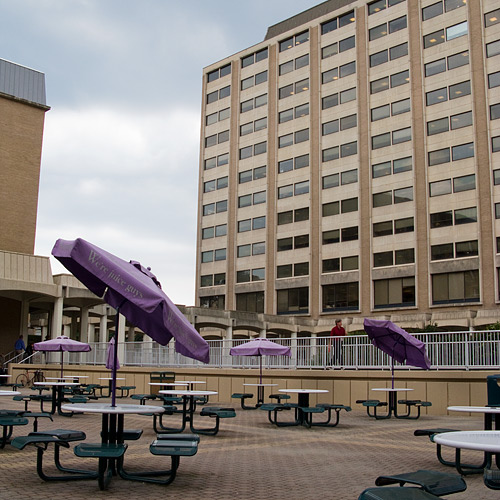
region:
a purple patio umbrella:
[50, 235, 210, 405]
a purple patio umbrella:
[363, 319, 432, 389]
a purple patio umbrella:
[229, 335, 291, 384]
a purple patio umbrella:
[33, 334, 90, 384]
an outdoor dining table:
[7, 401, 197, 487]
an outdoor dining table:
[258, 388, 350, 428]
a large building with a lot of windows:
[194, 0, 499, 366]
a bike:
[15, 367, 47, 390]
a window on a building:
[372, 275, 415, 311]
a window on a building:
[276, 287, 309, 317]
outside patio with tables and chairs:
[47, 223, 409, 467]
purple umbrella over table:
[36, 246, 266, 430]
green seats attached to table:
[79, 320, 256, 498]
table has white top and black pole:
[53, 381, 236, 493]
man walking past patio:
[297, 293, 443, 420]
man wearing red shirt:
[287, 301, 406, 425]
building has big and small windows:
[210, 140, 498, 381]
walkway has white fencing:
[182, 313, 435, 410]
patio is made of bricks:
[9, 386, 281, 491]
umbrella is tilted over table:
[51, 205, 276, 426]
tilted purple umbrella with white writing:
[50, 235, 215, 364]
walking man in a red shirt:
[327, 317, 348, 370]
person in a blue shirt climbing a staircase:
[11, 331, 29, 359]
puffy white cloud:
[41, 105, 211, 200]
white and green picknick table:
[10, 395, 205, 497]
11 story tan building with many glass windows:
[190, 0, 499, 367]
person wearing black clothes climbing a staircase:
[22, 337, 35, 363]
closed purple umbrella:
[101, 335, 124, 377]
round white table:
[54, 395, 169, 424]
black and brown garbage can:
[147, 367, 179, 398]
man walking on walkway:
[317, 301, 347, 377]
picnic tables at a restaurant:
[39, 237, 288, 479]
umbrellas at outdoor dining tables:
[41, 232, 286, 369]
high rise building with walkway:
[167, 22, 492, 322]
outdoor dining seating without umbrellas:
[268, 384, 489, 492]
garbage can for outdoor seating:
[144, 359, 185, 403]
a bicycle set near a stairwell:
[11, 365, 56, 391]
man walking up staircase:
[5, 293, 31, 370]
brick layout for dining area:
[226, 402, 406, 492]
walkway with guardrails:
[61, 335, 470, 389]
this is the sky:
[69, 13, 177, 67]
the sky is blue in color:
[88, 50, 143, 72]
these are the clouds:
[54, 115, 122, 147]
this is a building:
[210, 67, 494, 277]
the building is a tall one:
[277, 26, 374, 310]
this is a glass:
[294, 156, 309, 163]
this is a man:
[330, 317, 347, 333]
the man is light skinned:
[338, 320, 341, 323]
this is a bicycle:
[16, 369, 41, 380]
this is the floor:
[236, 429, 316, 496]